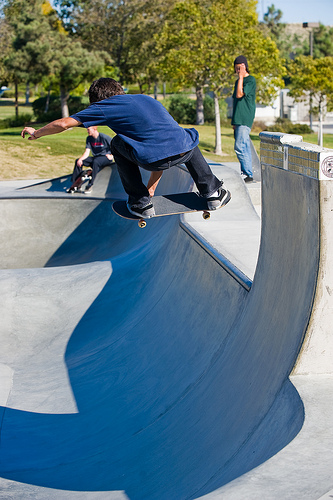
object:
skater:
[108, 160, 234, 249]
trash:
[279, 102, 313, 129]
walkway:
[2, 151, 266, 244]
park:
[38, 82, 331, 380]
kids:
[55, 80, 229, 214]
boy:
[228, 52, 260, 185]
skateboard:
[64, 169, 93, 192]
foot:
[71, 168, 85, 180]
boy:
[13, 71, 234, 220]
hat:
[224, 51, 265, 71]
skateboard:
[109, 181, 257, 225]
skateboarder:
[21, 73, 233, 249]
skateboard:
[110, 185, 231, 228]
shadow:
[2, 202, 252, 498]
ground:
[262, 106, 293, 134]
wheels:
[134, 210, 212, 227]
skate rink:
[0, 148, 331, 278]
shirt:
[230, 69, 257, 130]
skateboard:
[100, 168, 249, 232]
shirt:
[67, 90, 202, 163]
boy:
[63, 123, 114, 196]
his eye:
[221, 69, 271, 74]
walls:
[93, 83, 329, 498]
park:
[1, 3, 92, 44]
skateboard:
[109, 181, 235, 228]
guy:
[4, 68, 236, 230]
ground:
[194, 124, 217, 145]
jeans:
[234, 119, 257, 183]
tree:
[146, 0, 287, 154]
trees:
[0, 4, 332, 120]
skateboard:
[64, 158, 90, 193]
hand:
[145, 184, 155, 197]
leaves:
[157, 30, 259, 72]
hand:
[17, 121, 52, 145]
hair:
[85, 75, 128, 101]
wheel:
[134, 219, 148, 229]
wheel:
[200, 208, 213, 221]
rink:
[0, 153, 250, 291]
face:
[235, 59, 248, 72]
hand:
[234, 61, 248, 75]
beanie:
[234, 55, 247, 62]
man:
[73, 126, 116, 195]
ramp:
[0, 131, 333, 496]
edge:
[175, 164, 251, 291]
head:
[232, 53, 251, 76]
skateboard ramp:
[4, 190, 332, 495]